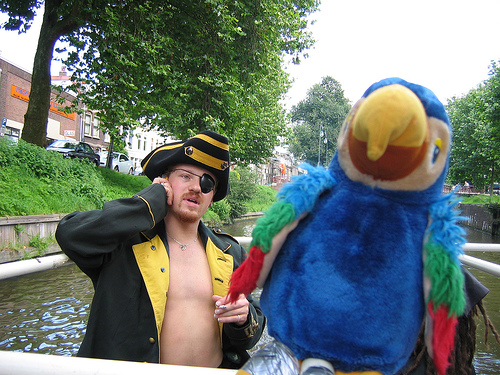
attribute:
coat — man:
[62, 190, 159, 352]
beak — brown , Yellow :
[334, 70, 434, 191]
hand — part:
[210, 290, 249, 326]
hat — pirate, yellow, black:
[140, 137, 235, 201]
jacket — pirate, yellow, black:
[58, 195, 258, 363]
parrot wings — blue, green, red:
[217, 159, 335, 311]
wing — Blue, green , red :
[420, 181, 468, 373]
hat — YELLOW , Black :
[136, 128, 231, 203]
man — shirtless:
[138, 136, 240, 338]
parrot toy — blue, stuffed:
[227, 75, 466, 372]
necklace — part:
[117, 197, 237, 279]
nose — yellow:
[350, 82, 425, 156]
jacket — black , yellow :
[35, 181, 269, 367]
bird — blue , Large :
[238, 52, 480, 354]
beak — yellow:
[324, 65, 435, 185]